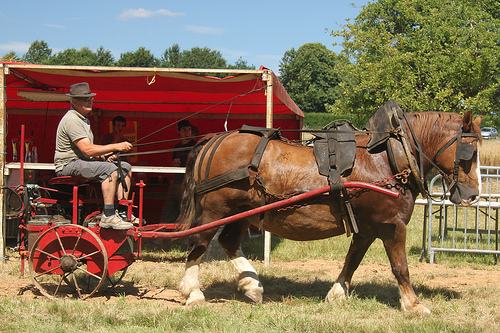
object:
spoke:
[75, 249, 100, 261]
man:
[52, 81, 148, 232]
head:
[69, 89, 93, 116]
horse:
[170, 99, 483, 320]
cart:
[13, 175, 148, 304]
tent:
[0, 58, 307, 239]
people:
[149, 118, 203, 250]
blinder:
[456, 140, 476, 162]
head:
[432, 109, 486, 210]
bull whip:
[109, 81, 282, 195]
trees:
[275, 41, 358, 112]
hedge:
[306, 119, 499, 138]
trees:
[317, 1, 499, 119]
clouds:
[181, 25, 227, 36]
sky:
[0, 0, 376, 78]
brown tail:
[170, 131, 216, 233]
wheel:
[27, 223, 110, 305]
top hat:
[61, 81, 97, 99]